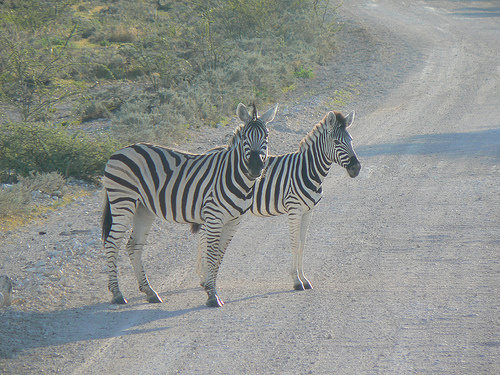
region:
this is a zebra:
[79, 130, 229, 305]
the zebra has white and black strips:
[149, 171, 208, 200]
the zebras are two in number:
[68, 115, 390, 271]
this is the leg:
[208, 210, 222, 302]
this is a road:
[404, 187, 472, 322]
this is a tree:
[27, 30, 102, 176]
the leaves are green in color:
[16, 12, 73, 93]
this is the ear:
[231, 101, 248, 122]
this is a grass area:
[26, 192, 38, 215]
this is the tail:
[88, 192, 112, 235]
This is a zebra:
[90, 99, 285, 319]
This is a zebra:
[165, 75, 388, 289]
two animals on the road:
[30, 10, 468, 361]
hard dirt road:
[352, 221, 492, 362]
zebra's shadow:
[0, 285, 176, 355]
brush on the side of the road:
[180, 15, 325, 85]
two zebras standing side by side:
[90, 90, 367, 310]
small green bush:
[0, 105, 97, 182]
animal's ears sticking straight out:
[227, 91, 279, 126]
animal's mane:
[295, 105, 337, 152]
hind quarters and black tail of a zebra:
[91, 140, 126, 242]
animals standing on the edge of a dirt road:
[76, 30, 474, 351]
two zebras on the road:
[69, 97, 363, 295]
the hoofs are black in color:
[191, 285, 236, 311]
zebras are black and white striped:
[96, 134, 364, 258]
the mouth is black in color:
[240, 138, 286, 180]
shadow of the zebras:
[32, 293, 178, 363]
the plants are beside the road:
[123, 26, 253, 98]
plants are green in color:
[200, 30, 275, 85]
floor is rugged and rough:
[377, 230, 467, 363]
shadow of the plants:
[390, 111, 495, 162]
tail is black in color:
[93, 190, 135, 238]